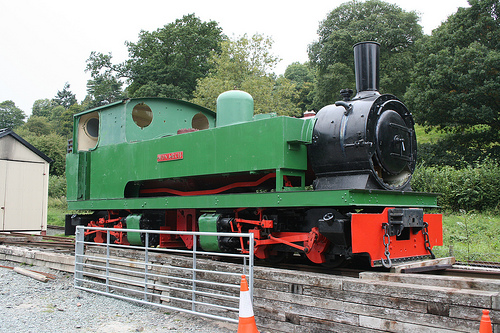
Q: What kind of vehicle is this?
A: Train.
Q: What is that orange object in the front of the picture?
A: A traffic cone.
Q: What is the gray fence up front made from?
A: Metal.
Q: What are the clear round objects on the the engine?
A: Windows.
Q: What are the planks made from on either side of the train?
A: Wood.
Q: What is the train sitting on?
A: Tracks.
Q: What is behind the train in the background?
A: Trees.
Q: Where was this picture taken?
A: At the train museum.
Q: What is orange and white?
A: The warning cones.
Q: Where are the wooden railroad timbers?
A: On the side of the tracks.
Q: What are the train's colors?
A: Green and orange.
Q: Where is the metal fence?
A: On the side of the train.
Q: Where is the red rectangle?
A: On the train's side.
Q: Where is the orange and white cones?
A: Next to the wooden timbers.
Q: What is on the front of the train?
A: A steam engine.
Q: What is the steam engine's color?
A: Black.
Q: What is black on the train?
A: The steam engine.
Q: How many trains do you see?
A: One.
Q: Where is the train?
A: On the tracks.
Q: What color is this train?
A: Green, black, and red.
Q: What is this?
A: A train.